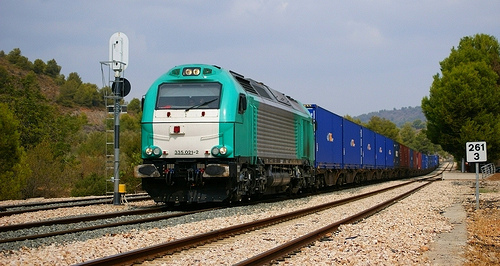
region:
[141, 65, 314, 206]
The front train car.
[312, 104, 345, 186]
A blue train car.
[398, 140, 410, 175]
A red train car.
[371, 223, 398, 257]
Part of the rocks.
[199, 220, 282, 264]
Part of the train tracks.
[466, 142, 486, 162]
A small white sign.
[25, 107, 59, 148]
Part of a tree.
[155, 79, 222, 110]
The front window on the train.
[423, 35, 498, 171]
A large green tree.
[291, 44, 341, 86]
Part of the blue sky.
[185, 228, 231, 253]
track made of steel.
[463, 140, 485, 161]
sign on the pole.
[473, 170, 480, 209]
pole supporting the sign.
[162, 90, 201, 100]
windshield on the train.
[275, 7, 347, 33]
clouds in the sky.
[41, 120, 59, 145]
leaves on the tree.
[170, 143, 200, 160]
number on the train.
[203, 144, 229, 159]
headlight on the train.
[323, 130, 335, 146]
logo on the blue train car.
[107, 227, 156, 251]
pebbles near the tracks.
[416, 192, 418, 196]
part of a rail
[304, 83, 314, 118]
part of a train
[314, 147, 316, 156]
edge of a train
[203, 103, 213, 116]
part of a window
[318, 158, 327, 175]
side of a train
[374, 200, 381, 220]
part of a rail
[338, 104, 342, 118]
edge of a window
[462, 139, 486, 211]
white and black sign on side of railroad track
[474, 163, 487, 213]
pole attaching sign into ground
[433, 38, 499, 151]
tall green tree behind the train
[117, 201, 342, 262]
brown railroad tracks on the ground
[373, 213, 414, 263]
gravel on the ground next to train tracks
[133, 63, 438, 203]
blue train on the tracks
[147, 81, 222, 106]
windshield on the front of train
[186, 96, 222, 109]
windshield wiper on window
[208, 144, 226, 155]
headlight on the blue train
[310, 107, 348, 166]
car on the blue train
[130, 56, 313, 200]
A green and white train engine.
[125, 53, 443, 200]
A train hauling freight cars.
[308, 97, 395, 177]
Five blue freight cars.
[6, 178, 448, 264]
Three sets of railroad tracks.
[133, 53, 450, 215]
Train is traveling on middle set of tracks.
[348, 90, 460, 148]
A small mountain in the distant.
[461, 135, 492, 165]
A white square sign.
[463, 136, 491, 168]
The numbers 261 3 on a square sign.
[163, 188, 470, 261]
Empty train track on the right side.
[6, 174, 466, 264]
Gravel in and around the tracks.